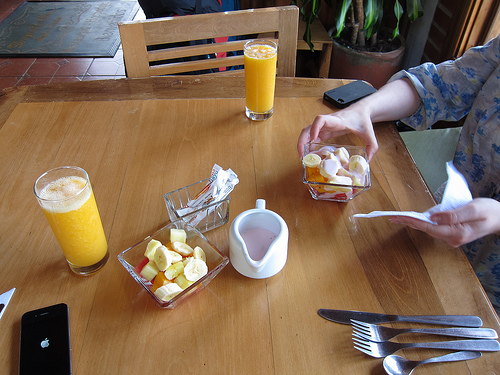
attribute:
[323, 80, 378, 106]
phone — black, upside-down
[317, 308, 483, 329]
knife — long, silver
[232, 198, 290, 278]
mug — white, empty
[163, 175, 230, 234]
dish — glass, square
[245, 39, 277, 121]
glass — full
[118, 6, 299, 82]
chair — light brown, empty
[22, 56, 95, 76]
tile — square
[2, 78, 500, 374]
table — wooden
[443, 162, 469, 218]
napkin — white